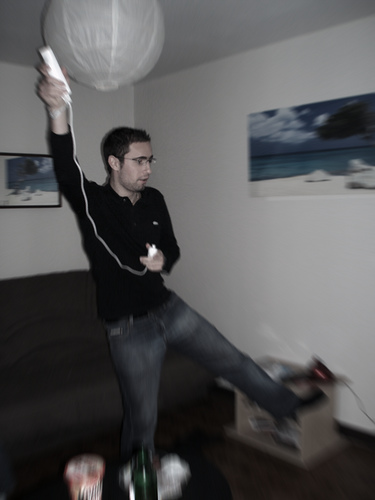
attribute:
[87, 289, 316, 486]
jeans — blue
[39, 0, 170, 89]
round lamp — white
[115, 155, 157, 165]
eyeglasses — eye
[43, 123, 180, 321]
shirt — black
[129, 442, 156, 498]
bottle — green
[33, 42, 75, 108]
remote — Wii video game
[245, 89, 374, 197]
poster — unframed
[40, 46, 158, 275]
remote controller — white, video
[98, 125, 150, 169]
hair — brown colored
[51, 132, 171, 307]
shirt — black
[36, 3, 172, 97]
lantern — white, paper, globe shaped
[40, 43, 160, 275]
game — video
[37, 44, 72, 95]
wiimote — white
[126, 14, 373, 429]
wall — white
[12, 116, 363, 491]
room — living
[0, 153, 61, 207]
frame — black